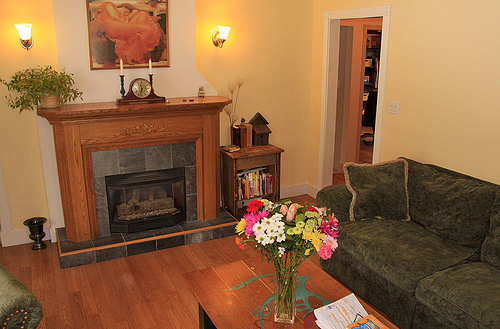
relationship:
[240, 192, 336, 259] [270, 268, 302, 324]
flowers in vase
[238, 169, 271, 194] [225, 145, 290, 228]
books in shelf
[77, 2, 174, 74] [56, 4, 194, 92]
painting on wall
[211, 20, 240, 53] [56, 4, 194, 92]
lamp on wall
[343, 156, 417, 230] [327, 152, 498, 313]
pillow on couch